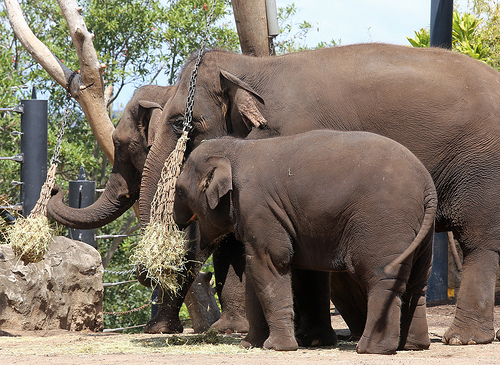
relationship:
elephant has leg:
[177, 123, 432, 350] [238, 247, 298, 347]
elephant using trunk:
[142, 39, 499, 346] [134, 129, 184, 230]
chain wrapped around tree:
[31, 71, 103, 158] [0, 3, 118, 164]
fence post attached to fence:
[18, 104, 50, 220] [5, 101, 55, 220]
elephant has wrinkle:
[177, 123, 432, 350] [269, 196, 299, 247]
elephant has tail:
[177, 123, 432, 350] [385, 171, 441, 283]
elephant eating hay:
[177, 123, 432, 350] [127, 216, 197, 291]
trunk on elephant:
[134, 129, 184, 230] [142, 39, 499, 346]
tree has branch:
[0, 3, 118, 164] [59, 4, 110, 94]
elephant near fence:
[142, 39, 499, 346] [5, 101, 55, 220]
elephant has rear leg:
[142, 39, 499, 346] [440, 215, 499, 343]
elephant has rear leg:
[177, 123, 432, 350] [351, 236, 410, 354]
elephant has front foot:
[177, 123, 432, 350] [265, 305, 299, 354]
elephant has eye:
[177, 123, 432, 350] [171, 184, 187, 201]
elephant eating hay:
[142, 39, 499, 346] [127, 216, 197, 291]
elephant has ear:
[177, 123, 432, 350] [199, 155, 236, 211]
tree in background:
[0, 3, 118, 164] [13, 4, 500, 184]